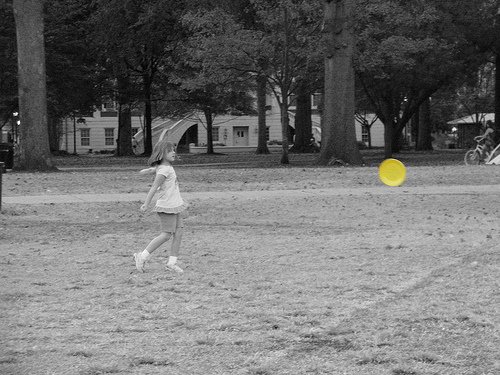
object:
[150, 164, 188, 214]
shirt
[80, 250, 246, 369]
ground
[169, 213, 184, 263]
leg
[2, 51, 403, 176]
building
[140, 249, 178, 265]
socks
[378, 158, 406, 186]
flying disc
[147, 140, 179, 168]
hair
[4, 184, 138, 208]
grey path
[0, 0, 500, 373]
photo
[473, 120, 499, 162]
person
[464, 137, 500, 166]
bike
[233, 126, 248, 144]
doors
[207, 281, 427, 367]
grass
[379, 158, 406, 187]
disc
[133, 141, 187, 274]
girl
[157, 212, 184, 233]
shorts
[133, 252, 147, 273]
shoes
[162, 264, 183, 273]
shoes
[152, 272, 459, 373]
playing area